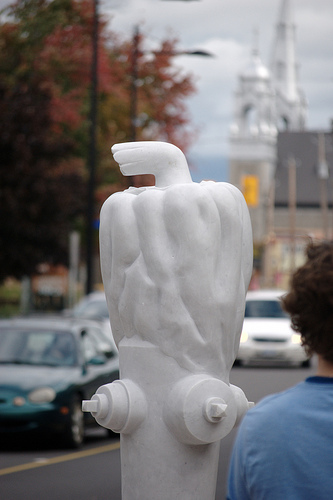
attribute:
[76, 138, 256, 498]
hydrant — smooth, white, decorated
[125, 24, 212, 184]
lamp post — large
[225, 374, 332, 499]
shirt — blue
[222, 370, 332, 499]
t-shirt — blue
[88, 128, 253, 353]
statue — modern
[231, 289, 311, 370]
car — blue, white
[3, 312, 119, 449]
car — dark green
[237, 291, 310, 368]
car — white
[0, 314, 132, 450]
car — green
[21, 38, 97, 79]
leaves — brown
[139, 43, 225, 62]
street light — distant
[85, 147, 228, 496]
sculpture — modern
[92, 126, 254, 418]
top — large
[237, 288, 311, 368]
car/lights — white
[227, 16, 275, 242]
tower — distant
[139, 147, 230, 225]
statue — large, white